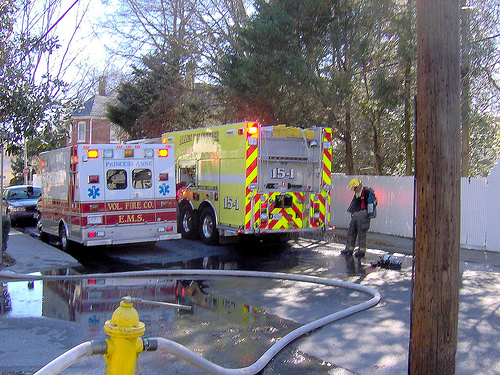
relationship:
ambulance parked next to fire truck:
[31, 142, 185, 249] [160, 120, 333, 246]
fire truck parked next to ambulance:
[160, 120, 333, 246] [31, 142, 185, 249]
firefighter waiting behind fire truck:
[335, 171, 381, 277] [167, 93, 345, 256]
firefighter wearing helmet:
[340, 177, 378, 258] [344, 176, 360, 191]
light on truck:
[229, 114, 272, 154] [152, 111, 373, 278]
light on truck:
[246, 126, 260, 136] [154, 95, 376, 269]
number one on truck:
[289, 167, 296, 180] [166, 100, 338, 245]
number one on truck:
[289, 167, 296, 178] [161, 121, 335, 242]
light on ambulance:
[158, 147, 170, 156] [31, 142, 185, 249]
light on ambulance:
[86, 149, 98, 159] [31, 142, 185, 249]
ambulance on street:
[23, 140, 188, 266] [3, 174, 490, 373]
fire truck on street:
[160, 120, 333, 246] [3, 174, 490, 373]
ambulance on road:
[31, 142, 185, 249] [0, 226, 499, 374]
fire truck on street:
[126, 120, 337, 247] [2, 217, 498, 373]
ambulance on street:
[31, 142, 185, 249] [2, 217, 498, 373]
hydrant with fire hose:
[100, 291, 150, 373] [43, 336, 106, 373]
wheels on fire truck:
[182, 203, 215, 234] [176, 129, 332, 231]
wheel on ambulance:
[57, 220, 69, 252] [31, 142, 185, 249]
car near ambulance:
[0, 184, 37, 225] [31, 142, 185, 249]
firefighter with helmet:
[340, 177, 378, 258] [341, 168, 368, 190]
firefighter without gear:
[340, 177, 378, 258] [338, 211, 381, 261]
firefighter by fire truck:
[340, 177, 378, 258] [171, 122, 336, 238]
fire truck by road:
[160, 120, 333, 246] [20, 266, 205, 356]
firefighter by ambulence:
[340, 177, 378, 258] [44, 126, 224, 261]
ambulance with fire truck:
[31, 142, 185, 249] [241, 130, 331, 224]